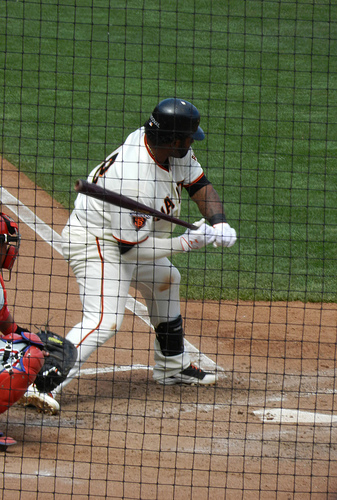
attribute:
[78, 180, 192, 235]
bat — black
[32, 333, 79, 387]
glove — black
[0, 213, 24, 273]
mask — red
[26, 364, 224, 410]
shoes — white, black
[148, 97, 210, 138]
helmet — shiny, black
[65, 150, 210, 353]
uniform — white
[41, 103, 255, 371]
player — playing ball, playing, batting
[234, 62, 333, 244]
ground — green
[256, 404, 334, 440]
base — white, small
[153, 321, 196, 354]
gear — black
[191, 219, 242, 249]
gloves — white